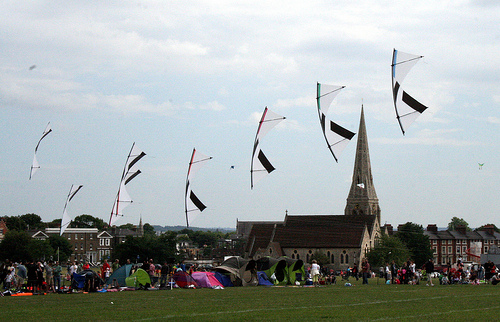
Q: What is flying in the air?
A: Several kites.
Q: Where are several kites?
A: Flying.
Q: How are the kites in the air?
A: Several kites are flying.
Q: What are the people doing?
A: Flying several kites.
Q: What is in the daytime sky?
A: Clouds.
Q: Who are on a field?
A: People are on a field.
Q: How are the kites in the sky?
A: Seven kites.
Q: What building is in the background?
A: Church.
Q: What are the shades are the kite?
A: Blue black and white.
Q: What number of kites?
A: Seven.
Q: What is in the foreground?
A: Green grass.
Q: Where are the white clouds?
A: In the sky.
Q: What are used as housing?
A: Tents.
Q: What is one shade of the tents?
A: Black.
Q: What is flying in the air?
A: Kites.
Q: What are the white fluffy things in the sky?
A: Clouds.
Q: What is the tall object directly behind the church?
A: A spire.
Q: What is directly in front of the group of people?
A: A grassy field.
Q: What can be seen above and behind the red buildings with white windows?
A: Trees.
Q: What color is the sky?
A: Blue.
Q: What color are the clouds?
A: White.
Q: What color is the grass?
A: Green.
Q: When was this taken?
A: During the day.